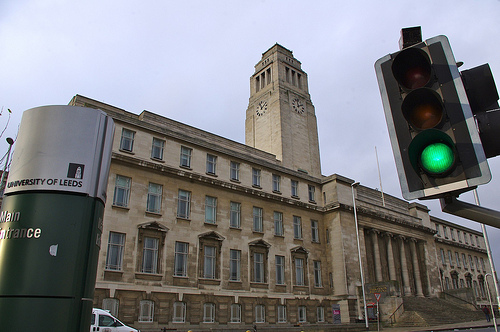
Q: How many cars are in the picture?
A: One.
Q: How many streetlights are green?
A: One.